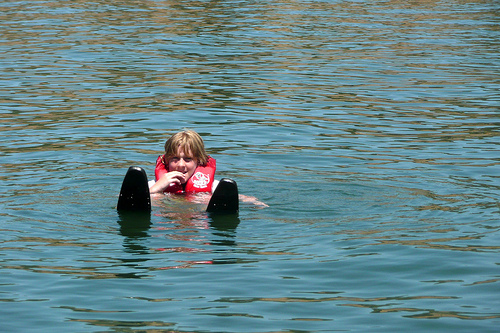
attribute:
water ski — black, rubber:
[113, 158, 155, 206]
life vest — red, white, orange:
[160, 159, 213, 191]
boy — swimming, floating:
[140, 137, 233, 206]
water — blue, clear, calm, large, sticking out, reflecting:
[50, 56, 460, 305]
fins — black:
[117, 177, 235, 215]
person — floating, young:
[141, 116, 207, 234]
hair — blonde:
[188, 129, 208, 161]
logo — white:
[193, 172, 204, 192]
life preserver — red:
[150, 158, 247, 195]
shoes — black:
[125, 169, 246, 203]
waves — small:
[225, 74, 417, 126]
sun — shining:
[168, 18, 382, 68]